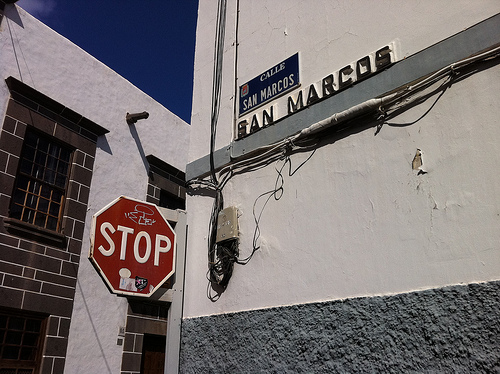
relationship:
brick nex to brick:
[69, 147, 87, 167] [62, 177, 84, 202]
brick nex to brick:
[62, 177, 84, 202] [57, 213, 77, 238]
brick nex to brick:
[55, 255, 82, 280] [17, 262, 39, 280]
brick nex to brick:
[11, 283, 38, 295] [70, 220, 84, 238]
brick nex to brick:
[66, 192, 88, 217] [40, 282, 82, 295]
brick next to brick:
[63, 199, 88, 223] [20, 289, 73, 312]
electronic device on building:
[211, 201, 243, 257] [190, 4, 497, 372]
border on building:
[167, 7, 227, 171] [9, 14, 209, 371]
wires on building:
[184, 38, 500, 302] [190, 4, 497, 372]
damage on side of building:
[405, 147, 430, 181] [190, 4, 497, 372]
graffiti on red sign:
[125, 200, 156, 225] [88, 190, 178, 298]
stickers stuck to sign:
[118, 279, 146, 289] [79, 188, 171, 297]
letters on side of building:
[230, 67, 414, 122] [190, 4, 497, 372]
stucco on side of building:
[177, 289, 485, 368] [140, 4, 484, 372]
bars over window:
[54, 192, 61, 236] [14, 127, 60, 229]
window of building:
[14, 127, 60, 229] [1, 108, 182, 372]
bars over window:
[30, 182, 40, 224] [14, 127, 60, 229]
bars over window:
[47, 187, 53, 227] [14, 127, 60, 229]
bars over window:
[18, 180, 26, 226] [14, 127, 60, 229]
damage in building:
[411, 149, 429, 173] [190, 4, 497, 372]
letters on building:
[237, 45, 393, 139] [190, 4, 497, 372]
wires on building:
[184, 51, 483, 204] [0, 0, 500, 372]